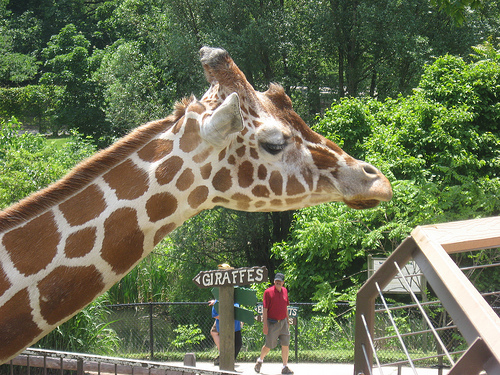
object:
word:
[255, 268, 264, 280]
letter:
[202, 274, 209, 286]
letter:
[214, 273, 222, 286]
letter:
[222, 272, 232, 284]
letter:
[231, 271, 238, 284]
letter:
[239, 269, 247, 284]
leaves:
[63, 24, 72, 36]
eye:
[256, 127, 294, 157]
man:
[208, 299, 243, 367]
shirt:
[212, 300, 243, 332]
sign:
[193, 265, 268, 288]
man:
[255, 273, 294, 375]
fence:
[98, 301, 500, 366]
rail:
[106, 301, 354, 364]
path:
[105, 358, 463, 375]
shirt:
[263, 285, 288, 320]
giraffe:
[1, 45, 393, 366]